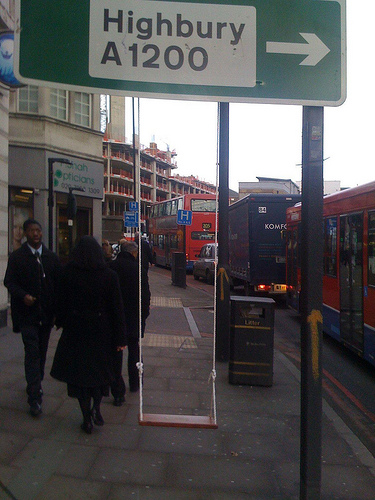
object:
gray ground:
[0, 263, 375, 500]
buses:
[285, 180, 374, 364]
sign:
[14, 0, 346, 107]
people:
[49, 236, 126, 438]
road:
[144, 262, 374, 455]